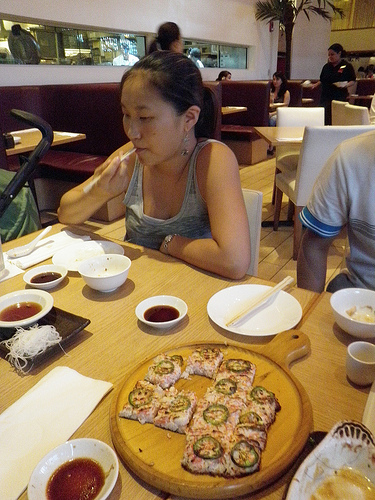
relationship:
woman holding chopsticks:
[57, 50, 252, 279] [82, 148, 137, 195]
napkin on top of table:
[1, 365, 114, 498] [1, 222, 373, 500]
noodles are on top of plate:
[0, 323, 64, 375] [0, 306, 91, 361]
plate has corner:
[0, 306, 91, 361] [15, 337, 42, 362]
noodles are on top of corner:
[0, 323, 64, 375] [15, 337, 42, 362]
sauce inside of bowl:
[144, 305, 180, 321] [134, 295, 188, 330]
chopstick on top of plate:
[225, 275, 293, 327] [208, 282, 302, 338]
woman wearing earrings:
[57, 50, 252, 279] [181, 130, 192, 157]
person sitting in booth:
[216, 68, 232, 82] [220, 81, 303, 166]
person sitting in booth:
[268, 72, 290, 156] [220, 81, 303, 166]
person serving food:
[310, 43, 357, 127] [299, 79, 350, 89]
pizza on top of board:
[118, 348, 281, 479] [109, 330, 314, 499]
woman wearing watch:
[57, 50, 252, 279] [161, 232, 181, 255]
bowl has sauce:
[134, 295, 188, 330] [144, 305, 180, 321]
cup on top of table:
[346, 340, 373, 388] [1, 222, 373, 500]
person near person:
[310, 43, 357, 127] [216, 68, 232, 82]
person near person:
[310, 43, 357, 127] [268, 72, 290, 156]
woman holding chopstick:
[57, 50, 252, 279] [82, 148, 137, 195]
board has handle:
[109, 330, 314, 499] [263, 328, 311, 364]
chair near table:
[272, 125, 375, 261] [1, 222, 373, 500]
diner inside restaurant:
[57, 50, 251, 281] [1, 1, 373, 497]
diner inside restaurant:
[297, 129, 374, 292] [1, 1, 373, 497]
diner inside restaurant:
[267, 71, 290, 154] [1, 1, 373, 497]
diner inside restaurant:
[215, 70, 232, 82] [1, 1, 373, 497]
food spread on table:
[1, 225, 373, 499] [1, 222, 373, 500]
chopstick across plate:
[225, 275, 293, 327] [208, 282, 302, 338]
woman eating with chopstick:
[57, 50, 252, 279] [82, 148, 137, 195]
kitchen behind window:
[1, 12, 147, 67] [1, 14, 149, 67]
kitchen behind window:
[182, 38, 248, 68] [181, 36, 247, 70]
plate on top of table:
[208, 282, 302, 338] [1, 222, 373, 500]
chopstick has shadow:
[224, 275, 290, 326] [233, 294, 287, 330]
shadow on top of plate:
[233, 294, 287, 330] [208, 282, 302, 338]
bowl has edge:
[77, 253, 131, 295] [76, 253, 132, 279]